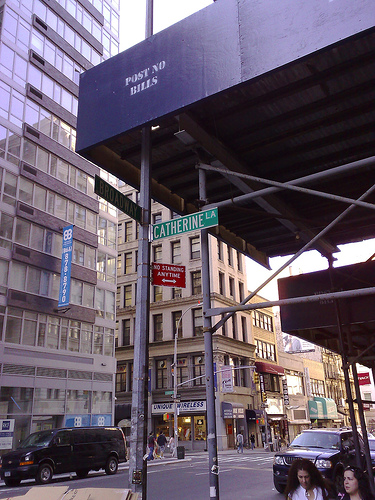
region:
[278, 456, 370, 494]
a couples heads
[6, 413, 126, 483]
a van parked on the sreet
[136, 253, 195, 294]
a sign on a pole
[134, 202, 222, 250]
a street sign on a pole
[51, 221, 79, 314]
a blue sign on a building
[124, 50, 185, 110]
writting on a blue metal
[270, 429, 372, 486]
trucked parked on street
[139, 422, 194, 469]
people on a street corner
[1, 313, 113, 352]
windows in a building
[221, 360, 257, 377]
a light on a pole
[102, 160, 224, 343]
Signs showing different roads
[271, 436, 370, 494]
Two women talking to each other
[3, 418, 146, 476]
Van parked beside the road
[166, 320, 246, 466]
Tall light beside the road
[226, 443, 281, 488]
White paint on the pavement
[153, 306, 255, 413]
Windows on side of the building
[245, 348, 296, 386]
Overhang over the window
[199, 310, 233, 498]
Metal pole on the street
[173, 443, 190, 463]
Trash can on corner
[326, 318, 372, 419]
Metal poles holding up ceiling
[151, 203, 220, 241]
a green street name sign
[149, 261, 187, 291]
a no parking sign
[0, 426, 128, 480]
a parked black SUV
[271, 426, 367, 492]
a parked black SUV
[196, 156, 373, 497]
erected grey metal scaffolding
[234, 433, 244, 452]
a pedestrian crossing street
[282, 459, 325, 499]
a pedestrian on sidewalk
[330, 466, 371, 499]
a pedestrian on sidewalk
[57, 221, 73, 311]
a business promotional sign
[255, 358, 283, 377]
a dark red awning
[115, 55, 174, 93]
post no bills stenciled on overhang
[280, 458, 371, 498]
woman walking down sidewalk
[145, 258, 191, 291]
red and white no standing anytime sign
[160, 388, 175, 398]
green and white street sign in background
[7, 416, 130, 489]
black van across the street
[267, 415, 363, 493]
dark suv parked on street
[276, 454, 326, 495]
long curly hair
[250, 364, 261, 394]
traffic light in the background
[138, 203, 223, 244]
green and white catherine la street sign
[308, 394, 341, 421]
green overhang in background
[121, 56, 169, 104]
words "post no bills" on the awning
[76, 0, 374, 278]
black awning over the sidewalk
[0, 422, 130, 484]
black van parked by the curb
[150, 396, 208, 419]
white and blue sign for the business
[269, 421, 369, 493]
black suv parked under the awning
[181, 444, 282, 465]
white cross walk in the intersection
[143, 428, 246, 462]
people walking in the intersection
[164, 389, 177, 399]
green and white street sign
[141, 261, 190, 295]
red and white warning sign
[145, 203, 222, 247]
street sign for Cathrine Lane